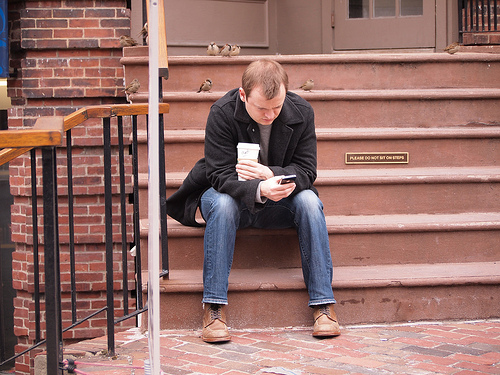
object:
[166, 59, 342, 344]
man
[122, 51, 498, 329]
stairs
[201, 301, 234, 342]
shoe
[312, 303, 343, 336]
shoe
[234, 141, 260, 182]
cup of coffee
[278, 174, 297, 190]
cell phone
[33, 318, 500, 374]
ground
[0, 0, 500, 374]
building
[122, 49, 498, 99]
step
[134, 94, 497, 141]
step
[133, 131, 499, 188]
step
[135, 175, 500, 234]
step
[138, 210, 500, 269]
step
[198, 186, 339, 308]
jeans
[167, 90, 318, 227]
jacket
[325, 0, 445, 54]
door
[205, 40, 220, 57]
bird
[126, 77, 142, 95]
bird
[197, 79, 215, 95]
bird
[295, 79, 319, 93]
bird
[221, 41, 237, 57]
bird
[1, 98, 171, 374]
railing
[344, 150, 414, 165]
outdoor sign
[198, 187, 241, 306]
leg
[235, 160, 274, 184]
hand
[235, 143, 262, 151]
lid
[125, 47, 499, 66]
top step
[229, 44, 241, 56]
bird